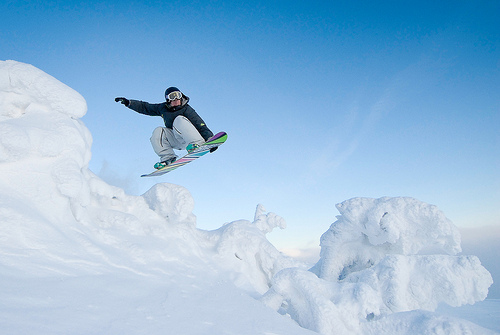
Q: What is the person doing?
A: Snowboarding.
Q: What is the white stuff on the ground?
A: Snow.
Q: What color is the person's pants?
A: White.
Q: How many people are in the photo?
A: One.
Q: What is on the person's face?
A: Goggles.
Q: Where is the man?
A: In the air.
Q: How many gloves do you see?
A: 2.